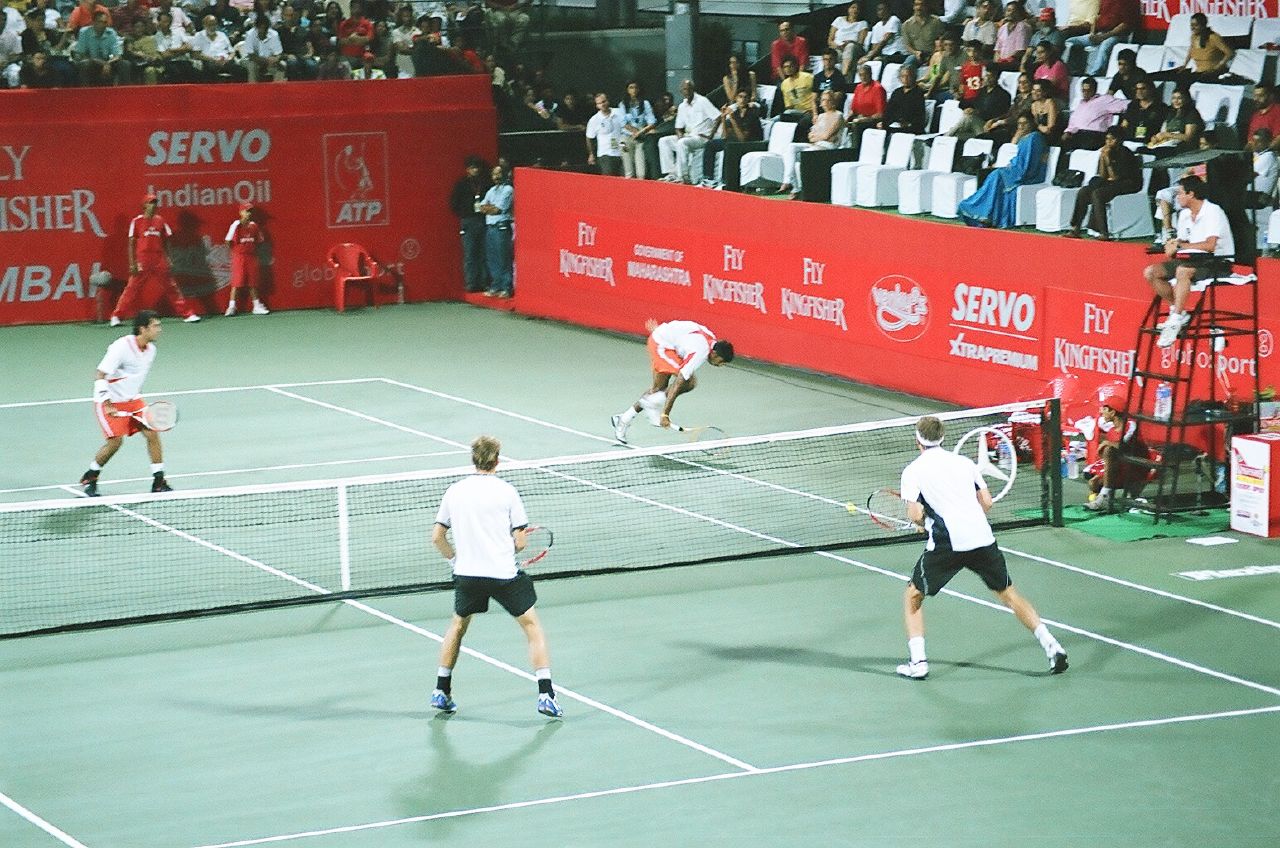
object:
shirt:
[896, 446, 998, 553]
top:
[433, 474, 531, 580]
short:
[451, 570, 538, 620]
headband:
[916, 428, 946, 446]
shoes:
[894, 643, 1067, 681]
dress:
[955, 130, 1050, 229]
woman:
[953, 112, 1049, 229]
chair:
[959, 116, 1073, 273]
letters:
[949, 282, 1040, 371]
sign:
[559, 222, 1272, 386]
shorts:
[910, 539, 1012, 596]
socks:
[536, 667, 556, 698]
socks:
[906, 624, 1062, 664]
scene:
[0, 0, 1280, 848]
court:
[650, 633, 853, 842]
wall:
[0, 73, 498, 329]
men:
[77, 310, 1069, 720]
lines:
[0, 377, 1280, 815]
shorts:
[453, 569, 540, 619]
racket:
[455, 526, 555, 591]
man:
[108, 194, 203, 327]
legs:
[108, 253, 201, 326]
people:
[6, 10, 1237, 347]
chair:
[829, 130, 882, 197]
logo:
[559, 222, 614, 289]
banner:
[508, 162, 1278, 475]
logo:
[626, 243, 691, 287]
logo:
[701, 245, 768, 313]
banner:
[506, 166, 1280, 487]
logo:
[780, 257, 851, 331]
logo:
[864, 274, 933, 343]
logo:
[949, 282, 1038, 373]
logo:
[1054, 303, 1143, 388]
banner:
[502, 151, 1280, 420]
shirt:
[431, 474, 529, 581]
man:
[429, 434, 563, 720]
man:
[890, 415, 1069, 680]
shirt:
[652, 320, 719, 381]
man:
[610, 320, 736, 447]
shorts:
[95, 399, 156, 439]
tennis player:
[610, 318, 734, 445]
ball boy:
[224, 201, 271, 316]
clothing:
[224, 204, 271, 318]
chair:
[855, 132, 918, 209]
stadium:
[0, 0, 1280, 848]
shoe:
[538, 677, 566, 716]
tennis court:
[0, 297, 1276, 848]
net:
[0, 401, 1065, 642]